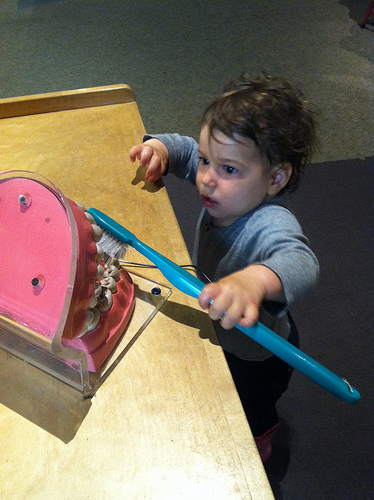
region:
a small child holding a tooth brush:
[93, 61, 354, 340]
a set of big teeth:
[16, 189, 168, 403]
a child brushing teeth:
[8, 100, 311, 402]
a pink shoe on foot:
[246, 414, 287, 469]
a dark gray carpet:
[328, 189, 373, 354]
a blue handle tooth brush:
[96, 204, 363, 397]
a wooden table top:
[5, 423, 261, 498]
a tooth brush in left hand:
[87, 198, 373, 382]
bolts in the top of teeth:
[29, 270, 51, 301]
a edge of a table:
[7, 80, 135, 124]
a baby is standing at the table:
[133, 69, 319, 456]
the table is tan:
[110, 299, 252, 486]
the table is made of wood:
[116, 323, 247, 486]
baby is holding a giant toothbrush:
[74, 173, 335, 424]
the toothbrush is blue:
[45, 159, 351, 453]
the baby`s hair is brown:
[167, 59, 326, 196]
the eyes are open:
[178, 144, 246, 181]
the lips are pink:
[183, 189, 226, 213]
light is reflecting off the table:
[80, 414, 227, 497]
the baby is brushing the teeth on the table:
[4, 161, 186, 381]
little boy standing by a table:
[126, 92, 330, 448]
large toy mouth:
[4, 167, 166, 397]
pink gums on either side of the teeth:
[69, 204, 141, 361]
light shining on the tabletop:
[106, 454, 244, 498]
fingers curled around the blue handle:
[195, 285, 268, 339]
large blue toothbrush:
[77, 206, 370, 410]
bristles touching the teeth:
[97, 234, 123, 262]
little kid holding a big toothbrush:
[85, 97, 372, 426]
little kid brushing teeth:
[3, 79, 361, 473]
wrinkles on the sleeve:
[262, 232, 323, 263]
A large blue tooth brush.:
[85, 206, 361, 405]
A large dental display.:
[0, 169, 175, 399]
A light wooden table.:
[0, 82, 275, 498]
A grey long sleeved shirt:
[143, 132, 320, 361]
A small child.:
[129, 65, 318, 460]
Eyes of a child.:
[196, 152, 232, 167]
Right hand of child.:
[195, 264, 260, 321]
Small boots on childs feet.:
[254, 421, 283, 462]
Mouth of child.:
[199, 192, 218, 208]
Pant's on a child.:
[223, 305, 330, 436]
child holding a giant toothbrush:
[90, 203, 325, 410]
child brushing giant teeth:
[64, 198, 125, 280]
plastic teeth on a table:
[6, 176, 156, 387]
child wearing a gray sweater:
[218, 211, 325, 321]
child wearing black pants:
[250, 345, 295, 448]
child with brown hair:
[216, 93, 295, 166]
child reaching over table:
[124, 118, 274, 333]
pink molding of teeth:
[18, 176, 146, 325]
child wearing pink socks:
[258, 435, 288, 471]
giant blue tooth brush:
[123, 221, 347, 388]